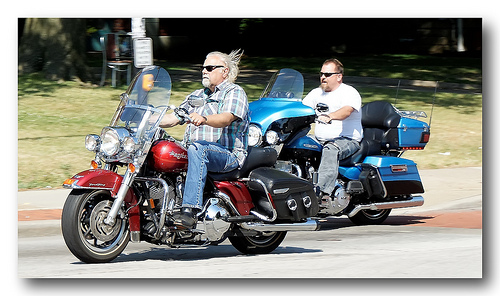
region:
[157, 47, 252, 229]
an older man riding on a bike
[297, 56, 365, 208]
a man riding on a bike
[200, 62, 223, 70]
the sunglasses of a man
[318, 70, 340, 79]
the sunglasses of a man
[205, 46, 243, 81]
the grey hair of a man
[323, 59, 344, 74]
the brown hair of a man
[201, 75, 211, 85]
the goatee of a man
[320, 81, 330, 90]
the goatee of a man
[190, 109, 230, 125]
the arm of a man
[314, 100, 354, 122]
the arm of a man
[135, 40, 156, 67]
a black and white sign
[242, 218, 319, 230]
a silver motorcycle pole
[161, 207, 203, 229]
a black male's boot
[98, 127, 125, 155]
a motorcycle light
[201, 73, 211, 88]
the beard of a man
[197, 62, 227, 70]
dark black sunglasses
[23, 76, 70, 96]
a shadow from a tree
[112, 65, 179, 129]
the windshield of the motorcycle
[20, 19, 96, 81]
the trunk of a tree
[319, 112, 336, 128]
the hand of a man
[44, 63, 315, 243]
red harley davidson motorcycle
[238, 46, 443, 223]
blue harley davidson motorcycle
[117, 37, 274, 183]
guy wearing cool sunglasses with white hair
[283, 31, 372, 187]
guy wearing a white shirt with black sunglasses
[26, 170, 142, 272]
motorcycle tire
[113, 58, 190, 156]
motorcycle visor glass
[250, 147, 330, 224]
back of motorcycle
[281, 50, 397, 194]
fat white guy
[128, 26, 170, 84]
white street sign in background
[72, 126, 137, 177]
headlight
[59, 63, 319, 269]
the front motorcycle is red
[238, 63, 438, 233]
the rear motorcycle is blue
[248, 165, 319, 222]
a black saddle bag on the red motorcycle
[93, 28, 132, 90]
a brown chair by the pole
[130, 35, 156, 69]
a sign on a metal pole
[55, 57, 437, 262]
the motorcycles are moving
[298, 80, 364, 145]
the tee shirt is white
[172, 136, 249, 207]
the man's jeans are blue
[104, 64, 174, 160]
the windshield on the red motorcycle is tall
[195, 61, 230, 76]
the sunglasses are black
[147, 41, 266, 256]
older man sitting down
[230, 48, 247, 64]
gray hir blowing in the wind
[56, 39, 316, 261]
older man on a red motorcycle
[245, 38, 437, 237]
man on a blue motorcycle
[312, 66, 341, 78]
thin black sunglasses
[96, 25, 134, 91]
silver chair on the grass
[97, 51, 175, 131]
small, rounded top, clear windshield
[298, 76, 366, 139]
bright white tee shirt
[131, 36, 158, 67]
white and black sign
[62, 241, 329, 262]
shadow